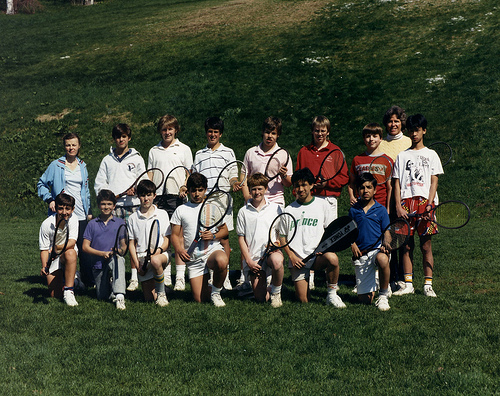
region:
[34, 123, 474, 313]
Group of tennis players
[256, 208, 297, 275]
Black tennis racket with clear laces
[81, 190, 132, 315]
Boy kneeling on one knee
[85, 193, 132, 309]
Boy wearing purple shirt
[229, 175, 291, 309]
Boy wearing white shirt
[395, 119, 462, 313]
Boy standing holding tennis racket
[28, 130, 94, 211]
Woman wearing light blue jacket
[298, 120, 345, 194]
Boy wearing red shirt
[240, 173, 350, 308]
Two boys kneeling next to each other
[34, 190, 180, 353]
Three boys kneeling on grass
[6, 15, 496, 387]
a boys tennis team is posing for a team picture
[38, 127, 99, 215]
a tennis coach is in the picture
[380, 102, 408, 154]
a lady coach is smiling for the photo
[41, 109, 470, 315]
the boys are holding their tennis rackets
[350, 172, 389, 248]
the boy has a blue polo shirt on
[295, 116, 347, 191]
the boy has a red long sleeve shirt on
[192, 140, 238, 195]
a white polo shirt has stripes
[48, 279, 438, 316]
the team is wearing white tennis shoes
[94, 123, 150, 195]
the player has a white hoodie on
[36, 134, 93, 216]
the coach has a blue sweater on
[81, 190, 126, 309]
boy in lavender shirt with tennis racket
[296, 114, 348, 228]
boy in red shirt with tennis racket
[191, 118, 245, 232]
boy in white, striped shirt with tennis racket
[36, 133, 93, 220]
person in pale blue jacket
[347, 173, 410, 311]
boy in blue shirt with tennis racket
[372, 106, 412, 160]
person in yellow shirt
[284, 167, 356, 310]
boy in white shirt with green print holding a covered tennis racket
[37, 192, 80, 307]
boy in white shirt with tennis racket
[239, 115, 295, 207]
boy in pink shirt with tennis racket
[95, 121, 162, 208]
boy in white hoodie with tennis racket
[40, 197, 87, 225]
head of a person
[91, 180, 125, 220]
head of a person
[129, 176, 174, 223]
head of a person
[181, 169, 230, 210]
head of a person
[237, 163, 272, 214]
head of a person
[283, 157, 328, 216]
head of a person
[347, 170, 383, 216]
head of a person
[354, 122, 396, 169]
head of a person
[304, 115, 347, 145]
head of a person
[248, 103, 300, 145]
head of a person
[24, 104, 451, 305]
a tennis team posing for a photo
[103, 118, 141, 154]
the head of a boy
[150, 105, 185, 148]
the head of a boy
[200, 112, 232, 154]
the head of a boy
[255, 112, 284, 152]
the head of a boy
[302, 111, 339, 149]
the head of a boy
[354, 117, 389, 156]
the head of a boy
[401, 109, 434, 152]
the head of a boy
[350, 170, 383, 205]
the head of a boy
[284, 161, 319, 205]
the head of a boy